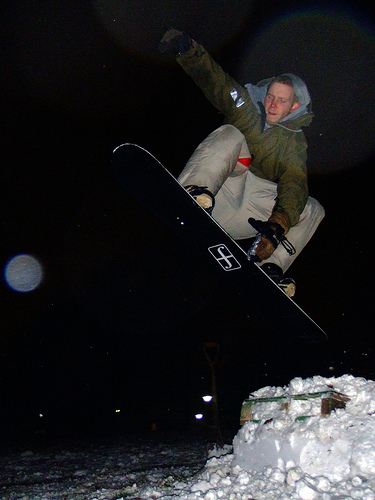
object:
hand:
[247, 210, 289, 263]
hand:
[157, 29, 192, 56]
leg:
[177, 123, 246, 213]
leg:
[256, 181, 325, 297]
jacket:
[176, 45, 315, 227]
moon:
[5, 255, 46, 292]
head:
[264, 75, 300, 126]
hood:
[245, 73, 315, 133]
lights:
[202, 395, 213, 402]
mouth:
[267, 110, 277, 117]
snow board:
[112, 143, 328, 341]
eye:
[280, 98, 286, 104]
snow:
[2, 372, 375, 500]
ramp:
[240, 390, 351, 425]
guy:
[158, 29, 325, 297]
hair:
[266, 74, 300, 109]